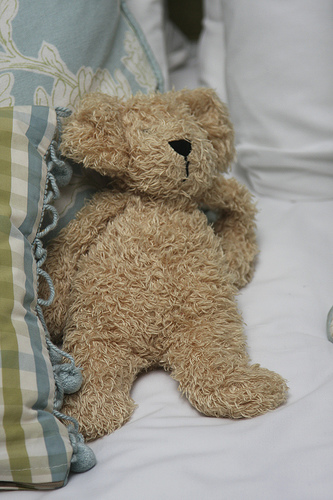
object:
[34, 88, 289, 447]
teddy bear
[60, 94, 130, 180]
ear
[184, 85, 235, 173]
ear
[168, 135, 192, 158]
nose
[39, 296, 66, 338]
paw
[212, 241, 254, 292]
paw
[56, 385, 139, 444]
paw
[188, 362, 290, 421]
paw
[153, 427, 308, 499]
sheet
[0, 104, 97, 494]
pillow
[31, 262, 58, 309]
fringe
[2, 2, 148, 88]
coverlet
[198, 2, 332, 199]
pillow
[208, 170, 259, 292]
arm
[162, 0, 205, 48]
shadow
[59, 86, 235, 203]
head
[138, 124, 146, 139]
eye